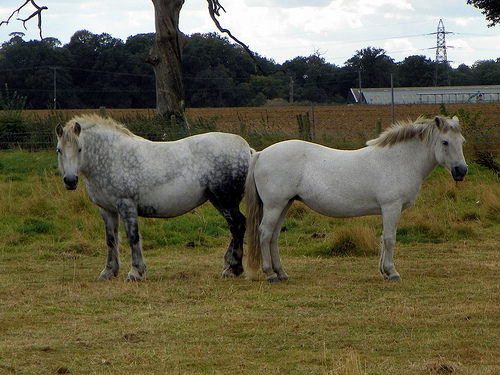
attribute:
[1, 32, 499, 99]
leaves — green 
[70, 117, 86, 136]
ear — in the picture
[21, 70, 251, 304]
horse — white, black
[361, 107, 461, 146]
mane — blown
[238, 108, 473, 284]
horse — white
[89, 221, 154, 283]
legs — black, white, horse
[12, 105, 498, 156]
fence — small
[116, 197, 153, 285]
leg — in the picture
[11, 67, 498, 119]
fence — grey, metal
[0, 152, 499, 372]
grass — short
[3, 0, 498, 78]
sky — blue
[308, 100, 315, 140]
post — grey, metal, fence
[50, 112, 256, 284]
horse — in the picture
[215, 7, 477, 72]
cloudy — white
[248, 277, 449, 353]
grass — in the picture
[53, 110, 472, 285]
horses — standing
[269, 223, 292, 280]
leg — in the picture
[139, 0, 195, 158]
tree trunk — old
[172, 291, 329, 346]
grass — green 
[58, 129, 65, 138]
ear — in the picture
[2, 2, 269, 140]
tree — in the picture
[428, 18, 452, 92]
pole — telephone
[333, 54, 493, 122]
building — in the picture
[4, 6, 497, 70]
skies — cloudy